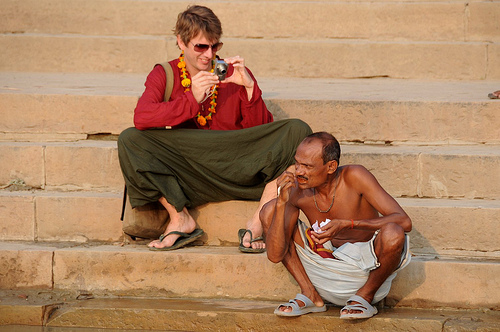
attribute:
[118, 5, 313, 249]
man — smiling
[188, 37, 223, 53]
sunglasses — tinted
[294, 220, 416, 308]
shorts — white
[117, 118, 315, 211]
pants — olive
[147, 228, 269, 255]
sandals — green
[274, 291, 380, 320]
sandals — grey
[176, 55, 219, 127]
necklace — yellow, orange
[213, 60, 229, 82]
camera — grey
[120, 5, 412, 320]
people — sitting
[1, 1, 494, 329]
steps — tan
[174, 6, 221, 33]
hair — brown